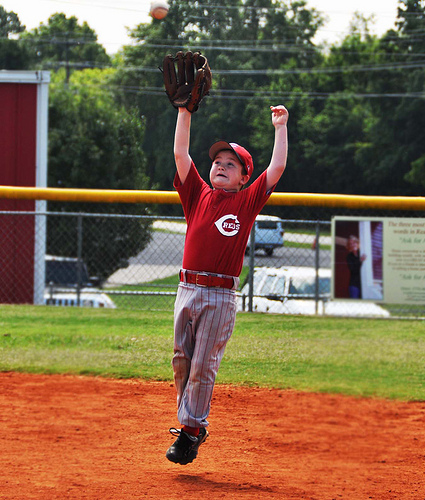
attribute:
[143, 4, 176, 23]
baseball — white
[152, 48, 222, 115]
mitt — dark, brown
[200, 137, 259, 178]
cap — red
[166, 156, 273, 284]
uniform — red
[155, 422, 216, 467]
cleats — baseball, pair, black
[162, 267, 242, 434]
pants — dark gray, gray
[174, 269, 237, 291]
belt — red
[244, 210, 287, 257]
jeep — silver, white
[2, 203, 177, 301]
fence — chainlink, metal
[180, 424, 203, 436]
socks — red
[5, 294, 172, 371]
grass — green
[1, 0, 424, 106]
electric wires — pole's, telephone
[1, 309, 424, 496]
baseball court — brown